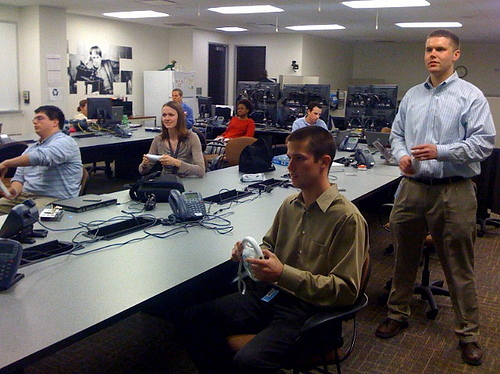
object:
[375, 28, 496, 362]
person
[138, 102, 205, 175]
person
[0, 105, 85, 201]
person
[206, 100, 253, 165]
person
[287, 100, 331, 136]
person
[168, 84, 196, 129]
person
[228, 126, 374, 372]
person